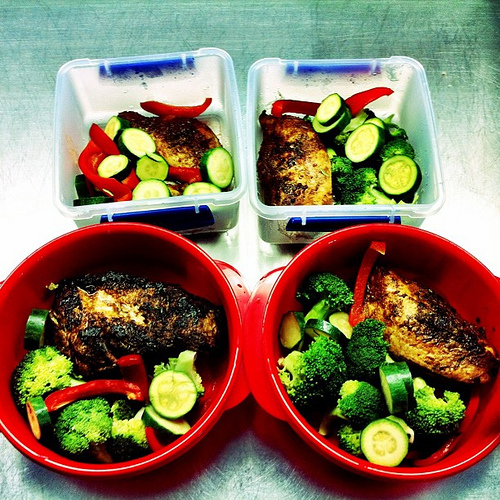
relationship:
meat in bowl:
[353, 257, 498, 391] [240, 215, 500, 499]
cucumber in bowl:
[374, 355, 420, 412] [240, 215, 500, 499]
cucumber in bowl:
[358, 410, 420, 472] [240, 215, 500, 499]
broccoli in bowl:
[342, 318, 390, 374] [240, 215, 500, 499]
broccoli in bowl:
[278, 331, 349, 415] [240, 215, 500, 499]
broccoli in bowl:
[329, 375, 386, 431] [240, 215, 500, 499]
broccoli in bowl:
[283, 269, 356, 333] [240, 215, 500, 499]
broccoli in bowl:
[406, 371, 468, 445] [240, 215, 500, 499]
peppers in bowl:
[43, 347, 156, 412] [2, 216, 259, 484]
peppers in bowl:
[140, 422, 169, 455] [2, 216, 259, 484]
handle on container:
[96, 51, 193, 78] [43, 42, 249, 247]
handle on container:
[93, 200, 220, 243] [43, 42, 249, 247]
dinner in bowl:
[277, 231, 499, 470] [240, 215, 500, 499]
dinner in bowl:
[11, 264, 224, 465] [2, 216, 259, 484]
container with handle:
[43, 42, 249, 247] [96, 51, 193, 78]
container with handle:
[43, 42, 249, 247] [93, 200, 220, 243]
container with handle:
[242, 48, 453, 248] [283, 57, 385, 78]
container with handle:
[242, 48, 453, 248] [287, 211, 403, 239]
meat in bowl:
[41, 261, 230, 385] [2, 216, 259, 484]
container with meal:
[43, 42, 249, 247] [69, 87, 240, 212]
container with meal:
[242, 48, 453, 248] [253, 76, 427, 212]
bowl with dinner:
[240, 215, 500, 499] [277, 231, 499, 470]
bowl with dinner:
[2, 216, 259, 484] [11, 264, 224, 465]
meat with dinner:
[353, 257, 498, 391] [277, 231, 499, 470]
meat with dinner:
[41, 261, 230, 385] [11, 264, 224, 465]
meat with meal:
[255, 99, 337, 209] [253, 76, 427, 212]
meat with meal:
[111, 107, 231, 181] [69, 87, 240, 212]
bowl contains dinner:
[2, 216, 259, 484] [11, 264, 224, 465]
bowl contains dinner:
[240, 215, 500, 499] [277, 231, 499, 470]